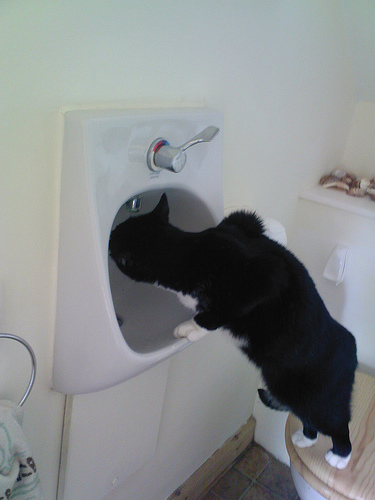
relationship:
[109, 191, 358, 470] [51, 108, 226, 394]
black cat drinks from urinal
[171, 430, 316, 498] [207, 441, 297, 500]
floor has tiles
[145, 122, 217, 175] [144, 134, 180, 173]
handle on harware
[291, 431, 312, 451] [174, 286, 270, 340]
cat paw on leg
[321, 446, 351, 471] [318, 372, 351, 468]
feet on leg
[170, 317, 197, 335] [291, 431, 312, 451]
foot on cat paw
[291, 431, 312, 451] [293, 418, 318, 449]
cat paw on leg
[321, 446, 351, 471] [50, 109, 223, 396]
feet on porceline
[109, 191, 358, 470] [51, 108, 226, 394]
black cat on urinal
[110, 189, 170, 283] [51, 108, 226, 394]
head in urinal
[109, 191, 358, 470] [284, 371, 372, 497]
black cat on toilet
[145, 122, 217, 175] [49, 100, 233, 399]
handle on sink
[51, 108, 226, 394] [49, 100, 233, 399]
urinal not a sink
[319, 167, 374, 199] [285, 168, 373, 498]
items on top of toilet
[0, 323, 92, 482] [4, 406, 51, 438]
hoop holding towel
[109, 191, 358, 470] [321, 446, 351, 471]
black cat has feet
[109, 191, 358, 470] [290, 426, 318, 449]
black cat has foot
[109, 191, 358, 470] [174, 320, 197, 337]
black cat has foot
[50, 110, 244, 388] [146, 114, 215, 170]
appliance has handle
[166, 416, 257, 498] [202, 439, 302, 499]
baseboard near floor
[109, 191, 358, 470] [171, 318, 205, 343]
black cat has foot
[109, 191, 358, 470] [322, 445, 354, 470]
black cat has foot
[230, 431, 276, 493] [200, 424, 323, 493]
tile on floor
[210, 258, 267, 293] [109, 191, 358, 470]
fur on black cat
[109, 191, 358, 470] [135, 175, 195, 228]
black cat has ear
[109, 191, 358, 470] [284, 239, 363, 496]
black cat on toilet